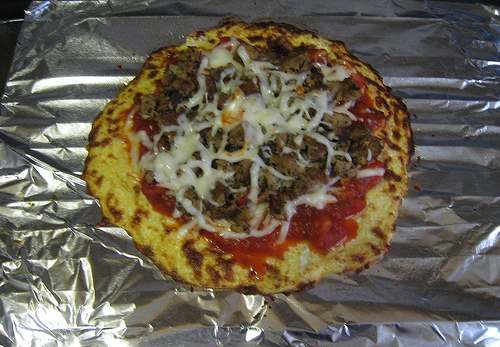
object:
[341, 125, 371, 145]
meat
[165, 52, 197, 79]
meat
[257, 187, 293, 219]
meat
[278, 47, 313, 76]
meat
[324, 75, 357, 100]
meat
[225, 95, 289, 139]
cheese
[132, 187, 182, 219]
sauce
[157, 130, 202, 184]
cheese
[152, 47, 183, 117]
meat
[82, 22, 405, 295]
cheese pizza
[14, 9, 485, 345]
foil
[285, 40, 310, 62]
beef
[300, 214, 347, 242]
sauce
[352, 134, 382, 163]
meat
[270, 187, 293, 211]
meat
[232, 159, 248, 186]
meat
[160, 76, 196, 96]
meat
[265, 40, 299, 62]
meat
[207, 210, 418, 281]
red sauce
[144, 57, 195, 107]
meat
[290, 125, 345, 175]
gound beef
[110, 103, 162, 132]
sauce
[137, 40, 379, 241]
toppings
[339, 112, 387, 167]
beef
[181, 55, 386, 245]
sauce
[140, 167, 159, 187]
gound beef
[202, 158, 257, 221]
meat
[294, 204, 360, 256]
sauce